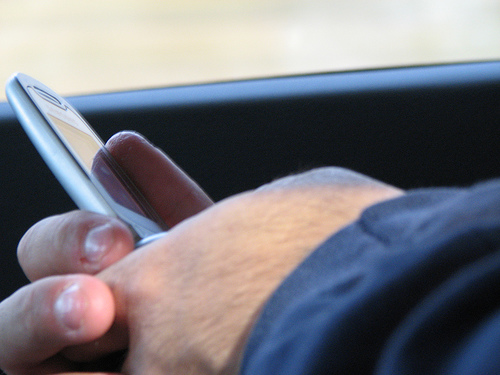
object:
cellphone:
[6, 75, 171, 249]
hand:
[61, 164, 404, 372]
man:
[0, 130, 500, 375]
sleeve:
[235, 174, 499, 375]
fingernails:
[82, 223, 116, 260]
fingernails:
[54, 284, 88, 331]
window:
[0, 3, 499, 102]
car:
[0, 0, 499, 303]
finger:
[17, 208, 136, 283]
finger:
[105, 130, 214, 229]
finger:
[0, 272, 118, 374]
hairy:
[93, 166, 405, 374]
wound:
[80, 257, 89, 264]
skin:
[0, 130, 406, 375]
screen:
[45, 112, 171, 239]